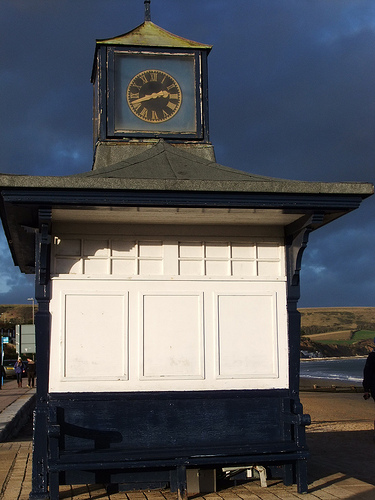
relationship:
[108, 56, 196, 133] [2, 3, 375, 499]
clock on structure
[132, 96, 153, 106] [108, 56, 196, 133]
hand of clock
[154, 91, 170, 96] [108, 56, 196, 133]
hand of clock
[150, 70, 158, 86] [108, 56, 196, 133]
number on clock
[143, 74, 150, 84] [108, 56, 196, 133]
number on clock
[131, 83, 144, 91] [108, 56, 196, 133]
number on clock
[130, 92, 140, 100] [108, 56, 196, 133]
number on clock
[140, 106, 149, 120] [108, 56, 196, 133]
number on clock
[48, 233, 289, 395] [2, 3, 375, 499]
wall on structure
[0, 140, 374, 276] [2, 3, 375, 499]
roof of structure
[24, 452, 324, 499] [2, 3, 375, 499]
base of structure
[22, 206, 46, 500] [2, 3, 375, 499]
edge of structure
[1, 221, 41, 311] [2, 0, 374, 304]
part of sky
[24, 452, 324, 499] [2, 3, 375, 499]
base of cupboard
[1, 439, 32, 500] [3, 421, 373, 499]
part of floor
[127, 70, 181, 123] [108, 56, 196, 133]
part of clock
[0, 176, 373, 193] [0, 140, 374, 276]
part of roof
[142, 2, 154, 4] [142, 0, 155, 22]
tip of tip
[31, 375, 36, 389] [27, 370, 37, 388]
part of pant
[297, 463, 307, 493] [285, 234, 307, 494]
part of post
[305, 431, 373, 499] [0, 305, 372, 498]
shadow on ground